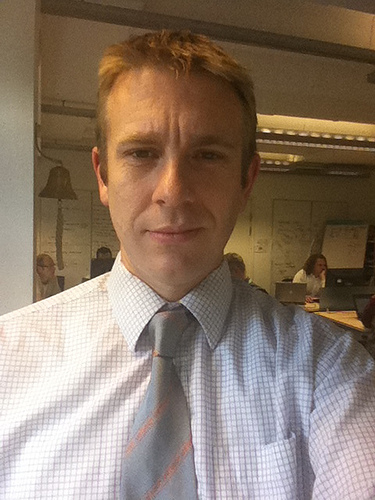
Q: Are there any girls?
A: No, there are no girls.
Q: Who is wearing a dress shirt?
A: The man is wearing a dress shirt.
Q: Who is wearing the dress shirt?
A: The man is wearing a dress shirt.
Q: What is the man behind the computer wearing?
A: The man is wearing a dress shirt.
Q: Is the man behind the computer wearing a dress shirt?
A: Yes, the man is wearing a dress shirt.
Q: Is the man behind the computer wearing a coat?
A: No, the man is wearing a dress shirt.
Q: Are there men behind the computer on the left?
A: Yes, there is a man behind the computer.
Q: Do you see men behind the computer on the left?
A: Yes, there is a man behind the computer.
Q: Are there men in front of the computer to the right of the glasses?
A: No, the man is behind the computer.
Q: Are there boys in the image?
A: No, there are no boys.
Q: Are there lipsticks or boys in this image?
A: No, there are no boys or lipsticks.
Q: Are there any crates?
A: No, there are no crates.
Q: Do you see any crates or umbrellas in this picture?
A: No, there are no crates or umbrellas.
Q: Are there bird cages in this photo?
A: No, there are no bird cages.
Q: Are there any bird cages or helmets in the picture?
A: No, there are no bird cages or helmets.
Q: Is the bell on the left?
A: Yes, the bell is on the left of the image.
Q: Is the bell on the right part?
A: No, the bell is on the left of the image.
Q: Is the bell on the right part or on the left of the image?
A: The bell is on the left of the image.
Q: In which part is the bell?
A: The bell is on the left of the image.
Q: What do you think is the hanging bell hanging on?
A: The bell is hanging on the wall.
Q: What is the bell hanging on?
A: The bell is hanging on the wall.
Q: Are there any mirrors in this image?
A: No, there are no mirrors.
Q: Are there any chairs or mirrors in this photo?
A: No, there are no mirrors or chairs.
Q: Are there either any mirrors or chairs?
A: No, there are no mirrors or chairs.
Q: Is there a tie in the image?
A: Yes, there is a tie.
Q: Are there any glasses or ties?
A: Yes, there is a tie.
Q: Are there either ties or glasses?
A: Yes, there is a tie.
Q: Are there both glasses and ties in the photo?
A: Yes, there are both a tie and glasses.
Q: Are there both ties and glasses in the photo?
A: Yes, there are both a tie and glasses.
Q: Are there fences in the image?
A: No, there are no fences.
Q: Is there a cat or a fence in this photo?
A: No, there are no fences or cats.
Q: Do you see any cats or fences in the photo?
A: No, there are no fences or cats.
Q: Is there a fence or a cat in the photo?
A: No, there are no fences or cats.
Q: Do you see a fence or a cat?
A: No, there are no fences or cats.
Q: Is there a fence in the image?
A: No, there are no fences.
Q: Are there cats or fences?
A: No, there are no fences or cats.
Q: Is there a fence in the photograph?
A: No, there are no fences.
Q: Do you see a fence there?
A: No, there are no fences.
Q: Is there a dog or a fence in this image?
A: No, there are no fences or dogs.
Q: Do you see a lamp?
A: No, there are no lamps.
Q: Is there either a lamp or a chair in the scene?
A: No, there are no lamps or chairs.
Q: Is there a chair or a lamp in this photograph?
A: No, there are no lamps or chairs.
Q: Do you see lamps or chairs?
A: No, there are no lamps or chairs.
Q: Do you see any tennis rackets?
A: No, there are no tennis rackets.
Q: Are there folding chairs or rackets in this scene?
A: No, there are no rackets or folding chairs.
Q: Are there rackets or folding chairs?
A: No, there are no rackets or folding chairs.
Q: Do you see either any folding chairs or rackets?
A: No, there are no rackets or folding chairs.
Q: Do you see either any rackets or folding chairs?
A: No, there are no rackets or folding chairs.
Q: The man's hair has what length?
A: The hair is long.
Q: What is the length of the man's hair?
A: The hair is long.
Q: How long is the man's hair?
A: The hair is long.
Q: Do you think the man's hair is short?
A: No, the hair is long.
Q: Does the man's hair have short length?
A: No, the hair is long.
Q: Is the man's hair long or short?
A: The hair is long.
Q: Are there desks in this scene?
A: Yes, there is a desk.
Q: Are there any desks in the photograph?
A: Yes, there is a desk.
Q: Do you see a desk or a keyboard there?
A: Yes, there is a desk.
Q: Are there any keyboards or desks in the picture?
A: Yes, there is a desk.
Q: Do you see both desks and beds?
A: No, there is a desk but no beds.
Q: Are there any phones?
A: No, there are no phones.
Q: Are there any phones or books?
A: No, there are no phones or books.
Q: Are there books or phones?
A: No, there are no phones or books.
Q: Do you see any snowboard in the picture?
A: No, there are no snowboards.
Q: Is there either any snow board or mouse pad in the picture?
A: No, there are no snowboards or mouse pads.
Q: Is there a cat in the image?
A: No, there are no cats.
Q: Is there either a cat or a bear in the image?
A: No, there are no cats or bears.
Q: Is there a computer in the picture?
A: Yes, there is a computer.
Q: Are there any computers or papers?
A: Yes, there is a computer.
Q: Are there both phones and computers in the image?
A: No, there is a computer but no phones.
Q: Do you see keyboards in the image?
A: No, there are no keyboards.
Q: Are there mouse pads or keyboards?
A: No, there are no keyboards or mouse pads.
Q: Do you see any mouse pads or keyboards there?
A: No, there are no keyboards or mouse pads.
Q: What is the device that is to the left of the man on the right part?
A: The device is a computer.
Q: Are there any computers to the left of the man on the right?
A: Yes, there is a computer to the left of the man.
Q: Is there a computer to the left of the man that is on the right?
A: Yes, there is a computer to the left of the man.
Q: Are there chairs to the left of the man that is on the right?
A: No, there is a computer to the left of the man.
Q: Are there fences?
A: No, there are no fences.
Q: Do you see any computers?
A: Yes, there is a computer.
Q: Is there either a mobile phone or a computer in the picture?
A: Yes, there is a computer.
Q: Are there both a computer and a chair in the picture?
A: No, there is a computer but no chairs.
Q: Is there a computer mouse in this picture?
A: No, there are no computer mice.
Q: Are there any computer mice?
A: No, there are no computer mice.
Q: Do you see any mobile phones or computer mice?
A: No, there are no computer mice or mobile phones.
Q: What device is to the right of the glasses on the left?
A: The device is a computer.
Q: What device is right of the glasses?
A: The device is a computer.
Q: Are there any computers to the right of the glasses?
A: Yes, there is a computer to the right of the glasses.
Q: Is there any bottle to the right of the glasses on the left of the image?
A: No, there is a computer to the right of the glasses.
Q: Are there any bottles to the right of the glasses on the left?
A: No, there is a computer to the right of the glasses.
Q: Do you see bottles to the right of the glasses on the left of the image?
A: No, there is a computer to the right of the glasses.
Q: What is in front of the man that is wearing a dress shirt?
A: The computer is in front of the man.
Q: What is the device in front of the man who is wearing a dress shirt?
A: The device is a computer.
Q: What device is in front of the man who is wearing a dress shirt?
A: The device is a computer.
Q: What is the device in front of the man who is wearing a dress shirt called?
A: The device is a computer.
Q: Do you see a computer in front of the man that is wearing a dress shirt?
A: Yes, there is a computer in front of the man.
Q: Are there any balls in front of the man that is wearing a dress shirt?
A: No, there is a computer in front of the man.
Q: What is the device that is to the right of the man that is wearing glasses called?
A: The device is a computer.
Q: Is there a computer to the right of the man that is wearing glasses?
A: Yes, there is a computer to the right of the man.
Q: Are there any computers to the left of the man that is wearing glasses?
A: No, the computer is to the right of the man.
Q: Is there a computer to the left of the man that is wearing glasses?
A: No, the computer is to the right of the man.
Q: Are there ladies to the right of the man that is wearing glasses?
A: No, there is a computer to the right of the man.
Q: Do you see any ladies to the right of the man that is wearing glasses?
A: No, there is a computer to the right of the man.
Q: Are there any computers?
A: Yes, there is a computer.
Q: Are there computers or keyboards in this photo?
A: Yes, there is a computer.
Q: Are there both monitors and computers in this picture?
A: No, there is a computer but no monitors.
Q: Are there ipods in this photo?
A: No, there are no ipods.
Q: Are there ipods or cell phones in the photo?
A: No, there are no ipods or cell phones.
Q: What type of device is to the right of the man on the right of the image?
A: The device is a computer.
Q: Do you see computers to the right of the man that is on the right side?
A: Yes, there is a computer to the right of the man.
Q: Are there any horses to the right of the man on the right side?
A: No, there is a computer to the right of the man.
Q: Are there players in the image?
A: No, there are no players.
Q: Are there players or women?
A: No, there are no players or women.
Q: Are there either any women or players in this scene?
A: No, there are no players or women.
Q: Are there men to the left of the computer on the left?
A: Yes, there is a man to the left of the computer.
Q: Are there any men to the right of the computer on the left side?
A: No, the man is to the left of the computer.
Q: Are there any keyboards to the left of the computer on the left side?
A: No, there is a man to the left of the computer.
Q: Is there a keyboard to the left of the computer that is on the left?
A: No, there is a man to the left of the computer.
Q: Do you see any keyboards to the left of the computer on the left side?
A: No, there is a man to the left of the computer.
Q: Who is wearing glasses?
A: The man is wearing glasses.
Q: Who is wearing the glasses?
A: The man is wearing glasses.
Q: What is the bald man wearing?
A: The man is wearing glasses.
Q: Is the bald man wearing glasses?
A: Yes, the man is wearing glasses.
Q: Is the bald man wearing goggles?
A: No, the man is wearing glasses.